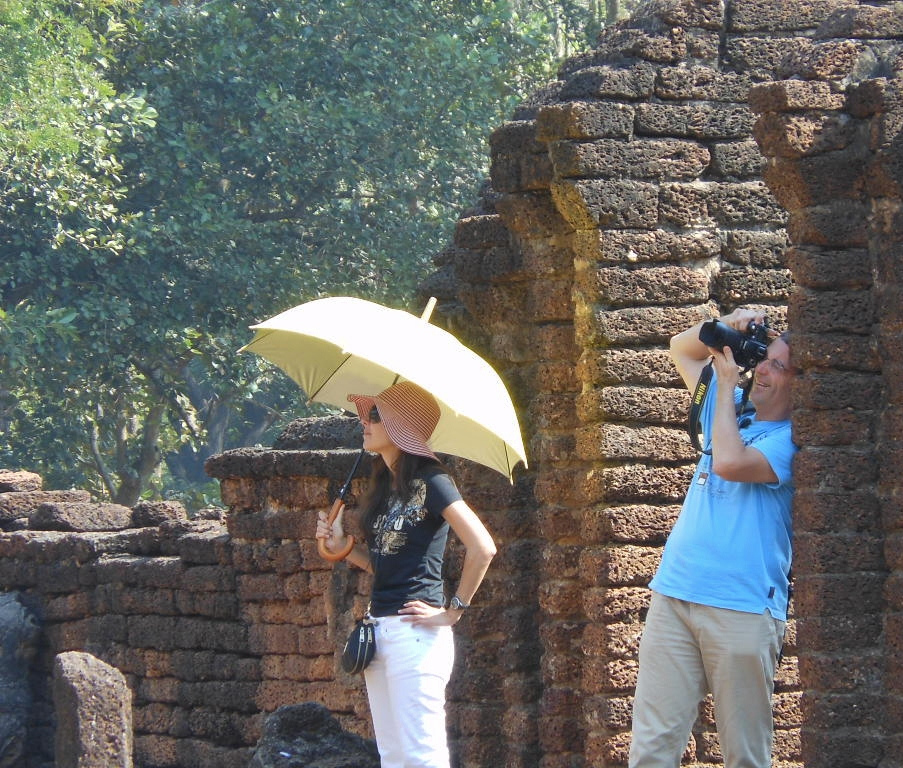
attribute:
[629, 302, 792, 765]
man — photographing, taking a picture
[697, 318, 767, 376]
camera — nikon, professional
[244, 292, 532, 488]
umbrella — yellow, wooden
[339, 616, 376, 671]
bag — black, zippered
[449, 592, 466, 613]
watch — black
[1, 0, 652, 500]
tree — existing, green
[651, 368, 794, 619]
shirt — blue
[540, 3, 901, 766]
wall — old, weathered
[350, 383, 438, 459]
hat — striped, straw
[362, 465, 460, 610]
shirt — black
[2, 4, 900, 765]
scene — outdoors, daytime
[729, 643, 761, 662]
object — rectangular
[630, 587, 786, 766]
pants — khaki, white